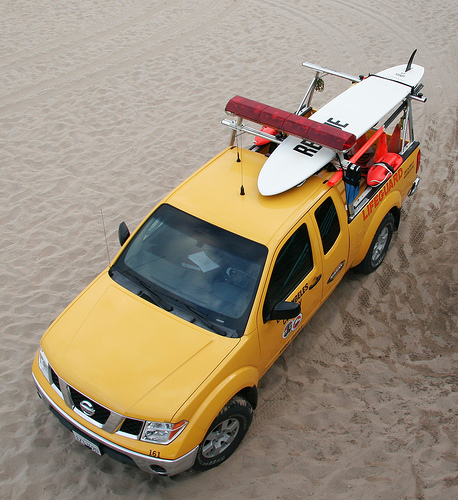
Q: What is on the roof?
A: A surfboard.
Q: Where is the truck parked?
A: On the beach.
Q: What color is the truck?
A: Yellow.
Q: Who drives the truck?
A: A lifeguard.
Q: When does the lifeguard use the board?
A: During breaks.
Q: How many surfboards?
A: 1.